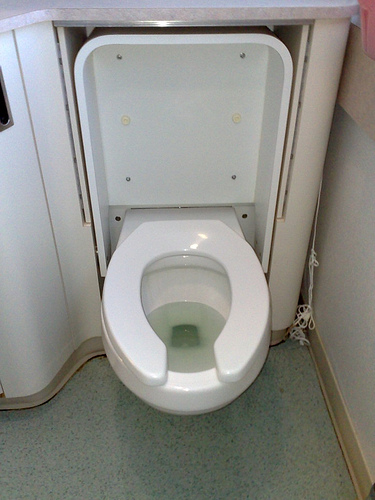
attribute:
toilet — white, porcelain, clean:
[97, 206, 271, 416]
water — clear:
[145, 300, 225, 372]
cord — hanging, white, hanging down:
[284, 172, 320, 349]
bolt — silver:
[115, 53, 124, 63]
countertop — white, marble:
[1, 2, 361, 33]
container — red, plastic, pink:
[358, 2, 374, 61]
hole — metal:
[2, 71, 16, 135]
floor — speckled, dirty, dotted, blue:
[1, 329, 359, 500]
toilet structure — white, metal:
[72, 27, 297, 282]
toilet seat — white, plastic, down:
[101, 219, 265, 384]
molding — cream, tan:
[0, 295, 375, 499]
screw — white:
[231, 112, 243, 125]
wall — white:
[295, 98, 374, 483]